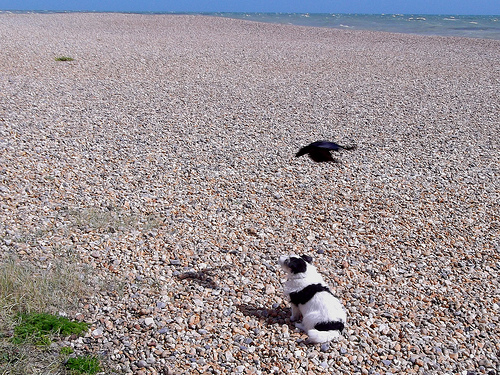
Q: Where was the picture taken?
A: It was taken at the beach.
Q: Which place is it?
A: It is a beach.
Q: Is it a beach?
A: Yes, it is a beach.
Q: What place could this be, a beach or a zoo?
A: It is a beach.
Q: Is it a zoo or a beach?
A: It is a beach.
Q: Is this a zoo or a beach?
A: It is a beach.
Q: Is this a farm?
A: No, it is a beach.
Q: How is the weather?
A: It is cloudless.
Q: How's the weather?
A: It is cloudless.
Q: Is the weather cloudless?
A: Yes, it is cloudless.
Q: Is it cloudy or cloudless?
A: It is cloudless.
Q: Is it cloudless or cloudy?
A: It is cloudless.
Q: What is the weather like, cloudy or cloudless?
A: It is cloudless.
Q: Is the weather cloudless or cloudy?
A: It is cloudless.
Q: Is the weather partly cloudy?
A: No, it is cloudless.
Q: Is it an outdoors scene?
A: Yes, it is outdoors.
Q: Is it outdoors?
A: Yes, it is outdoors.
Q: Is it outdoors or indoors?
A: It is outdoors.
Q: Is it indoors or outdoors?
A: It is outdoors.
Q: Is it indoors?
A: No, it is outdoors.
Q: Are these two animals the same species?
A: No, they are dogs and birds.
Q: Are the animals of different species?
A: Yes, they are dogs and birds.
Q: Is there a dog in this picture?
A: Yes, there is a dog.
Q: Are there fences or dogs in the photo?
A: Yes, there is a dog.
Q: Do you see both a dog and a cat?
A: No, there is a dog but no cats.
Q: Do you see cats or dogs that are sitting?
A: Yes, the dog is sitting.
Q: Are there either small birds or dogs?
A: Yes, there is a small dog.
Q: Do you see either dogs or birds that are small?
A: Yes, the dog is small.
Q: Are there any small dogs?
A: Yes, there is a small dog.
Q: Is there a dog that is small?
A: Yes, there is a dog that is small.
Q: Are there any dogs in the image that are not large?
A: Yes, there is a small dog.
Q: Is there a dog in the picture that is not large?
A: Yes, there is a small dog.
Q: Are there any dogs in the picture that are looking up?
A: Yes, there is a dog that is looking up.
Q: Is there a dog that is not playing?
A: Yes, there is a dog that is looking up.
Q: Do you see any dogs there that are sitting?
A: Yes, there is a dog that is sitting.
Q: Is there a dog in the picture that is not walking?
A: Yes, there is a dog that is sitting.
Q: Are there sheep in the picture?
A: No, there are no sheep.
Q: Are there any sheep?
A: No, there are no sheep.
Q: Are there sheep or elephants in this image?
A: No, there are no sheep or elephants.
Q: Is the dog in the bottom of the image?
A: Yes, the dog is in the bottom of the image.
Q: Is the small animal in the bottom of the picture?
A: Yes, the dog is in the bottom of the image.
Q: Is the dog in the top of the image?
A: No, the dog is in the bottom of the image.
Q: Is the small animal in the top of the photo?
A: No, the dog is in the bottom of the image.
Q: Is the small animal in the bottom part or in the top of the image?
A: The dog is in the bottom of the image.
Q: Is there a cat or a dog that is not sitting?
A: No, there is a dog but it is sitting.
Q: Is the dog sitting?
A: Yes, the dog is sitting.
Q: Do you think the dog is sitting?
A: Yes, the dog is sitting.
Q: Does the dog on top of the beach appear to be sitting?
A: Yes, the dog is sitting.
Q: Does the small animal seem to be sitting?
A: Yes, the dog is sitting.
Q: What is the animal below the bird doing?
A: The dog is sitting.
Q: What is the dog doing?
A: The dog is sitting.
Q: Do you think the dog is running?
A: No, the dog is sitting.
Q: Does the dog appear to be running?
A: No, the dog is sitting.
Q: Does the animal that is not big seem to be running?
A: No, the dog is sitting.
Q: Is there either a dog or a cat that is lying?
A: No, there is a dog but it is sitting.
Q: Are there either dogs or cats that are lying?
A: No, there is a dog but it is sitting.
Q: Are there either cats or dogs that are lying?
A: No, there is a dog but it is sitting.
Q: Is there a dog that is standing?
A: No, there is a dog but it is sitting.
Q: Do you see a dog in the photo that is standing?
A: No, there is a dog but it is sitting.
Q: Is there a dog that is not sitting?
A: No, there is a dog but it is sitting.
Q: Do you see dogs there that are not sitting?
A: No, there is a dog but it is sitting.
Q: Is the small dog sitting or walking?
A: The dog is sitting.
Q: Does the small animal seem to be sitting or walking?
A: The dog is sitting.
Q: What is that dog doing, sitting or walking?
A: The dog is sitting.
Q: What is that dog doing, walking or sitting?
A: The dog is sitting.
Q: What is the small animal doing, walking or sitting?
A: The dog is sitting.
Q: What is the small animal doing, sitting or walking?
A: The dog is sitting.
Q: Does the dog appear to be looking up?
A: Yes, the dog is looking up.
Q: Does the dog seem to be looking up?
A: Yes, the dog is looking up.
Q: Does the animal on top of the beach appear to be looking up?
A: Yes, the dog is looking up.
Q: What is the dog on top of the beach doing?
A: The dog is looking up.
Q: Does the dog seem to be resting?
A: No, the dog is looking up.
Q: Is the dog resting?
A: No, the dog is looking up.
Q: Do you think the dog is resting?
A: No, the dog is looking up.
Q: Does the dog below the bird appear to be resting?
A: No, the dog is looking up.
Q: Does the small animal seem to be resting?
A: No, the dog is looking up.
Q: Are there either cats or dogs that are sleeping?
A: No, there is a dog but it is looking up.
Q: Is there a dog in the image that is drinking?
A: No, there is a dog but it is looking up.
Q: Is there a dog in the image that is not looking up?
A: No, there is a dog but it is looking up.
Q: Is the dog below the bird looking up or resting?
A: The dog is looking up.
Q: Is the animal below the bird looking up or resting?
A: The dog is looking up.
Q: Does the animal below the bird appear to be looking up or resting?
A: The dog is looking up.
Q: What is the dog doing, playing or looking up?
A: The dog is looking up.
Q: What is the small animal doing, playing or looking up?
A: The dog is looking up.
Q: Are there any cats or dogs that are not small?
A: No, there is a dog but it is small.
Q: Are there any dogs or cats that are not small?
A: No, there is a dog but it is small.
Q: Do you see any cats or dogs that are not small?
A: No, there is a dog but it is small.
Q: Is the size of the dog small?
A: Yes, the dog is small.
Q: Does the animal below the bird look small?
A: Yes, the dog is small.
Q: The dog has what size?
A: The dog is small.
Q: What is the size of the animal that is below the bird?
A: The dog is small.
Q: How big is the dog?
A: The dog is small.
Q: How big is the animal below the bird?
A: The dog is small.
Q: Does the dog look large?
A: No, the dog is small.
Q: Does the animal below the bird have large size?
A: No, the dog is small.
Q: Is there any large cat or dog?
A: No, there is a dog but it is small.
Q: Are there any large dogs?
A: No, there is a dog but it is small.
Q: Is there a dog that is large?
A: No, there is a dog but it is small.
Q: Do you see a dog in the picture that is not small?
A: No, there is a dog but it is small.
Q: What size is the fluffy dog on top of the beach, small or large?
A: The dog is small.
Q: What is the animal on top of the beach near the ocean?
A: The animal is a dog.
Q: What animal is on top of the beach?
A: The animal is a dog.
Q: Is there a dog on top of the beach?
A: Yes, there is a dog on top of the beach.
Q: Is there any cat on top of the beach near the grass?
A: No, there is a dog on top of the beach.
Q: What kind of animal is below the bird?
A: The animal is a dog.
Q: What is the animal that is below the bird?
A: The animal is a dog.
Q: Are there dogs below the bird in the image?
A: Yes, there is a dog below the bird.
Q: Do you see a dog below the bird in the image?
A: Yes, there is a dog below the bird.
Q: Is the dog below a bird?
A: Yes, the dog is below a bird.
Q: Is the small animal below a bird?
A: Yes, the dog is below a bird.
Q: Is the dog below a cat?
A: No, the dog is below a bird.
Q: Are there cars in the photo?
A: No, there are no cars.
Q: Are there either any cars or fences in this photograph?
A: No, there are no cars or fences.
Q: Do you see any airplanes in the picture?
A: No, there are no airplanes.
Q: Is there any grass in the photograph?
A: Yes, there is grass.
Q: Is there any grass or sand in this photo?
A: Yes, there is grass.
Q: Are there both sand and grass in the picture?
A: No, there is grass but no sand.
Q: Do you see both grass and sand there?
A: No, there is grass but no sand.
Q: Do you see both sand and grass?
A: No, there is grass but no sand.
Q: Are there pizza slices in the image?
A: No, there are no pizza slices.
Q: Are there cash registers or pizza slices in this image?
A: No, there are no pizza slices or cash registers.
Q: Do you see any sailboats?
A: No, there are no sailboats.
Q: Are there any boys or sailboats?
A: No, there are no sailboats or boys.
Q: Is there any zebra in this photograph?
A: No, there are no zebras.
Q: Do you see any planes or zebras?
A: No, there are no zebras or planes.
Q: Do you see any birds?
A: Yes, there is a bird.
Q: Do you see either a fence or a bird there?
A: Yes, there is a bird.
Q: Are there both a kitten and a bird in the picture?
A: No, there is a bird but no kittens.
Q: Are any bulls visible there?
A: No, there are no bulls.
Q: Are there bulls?
A: No, there are no bulls.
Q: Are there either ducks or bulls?
A: No, there are no bulls or ducks.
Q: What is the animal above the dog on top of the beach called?
A: The animal is a bird.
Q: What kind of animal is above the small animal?
A: The animal is a bird.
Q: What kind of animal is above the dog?
A: The animal is a bird.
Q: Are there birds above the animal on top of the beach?
A: Yes, there is a bird above the dog.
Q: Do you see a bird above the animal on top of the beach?
A: Yes, there is a bird above the dog.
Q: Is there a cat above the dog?
A: No, there is a bird above the dog.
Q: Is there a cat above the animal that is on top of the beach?
A: No, there is a bird above the dog.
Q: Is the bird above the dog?
A: Yes, the bird is above the dog.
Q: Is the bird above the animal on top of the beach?
A: Yes, the bird is above the dog.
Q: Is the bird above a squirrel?
A: No, the bird is above the dog.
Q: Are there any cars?
A: No, there are no cars.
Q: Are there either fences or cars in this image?
A: No, there are no cars or fences.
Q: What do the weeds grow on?
A: The weeds grow on the beach.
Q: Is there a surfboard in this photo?
A: No, there are no surfboards.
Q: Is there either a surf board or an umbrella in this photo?
A: No, there are no surfboards or umbrellas.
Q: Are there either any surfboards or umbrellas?
A: No, there are no surfboards or umbrellas.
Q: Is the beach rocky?
A: Yes, the beach is rocky.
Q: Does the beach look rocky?
A: Yes, the beach is rocky.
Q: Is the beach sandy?
A: No, the beach is rocky.